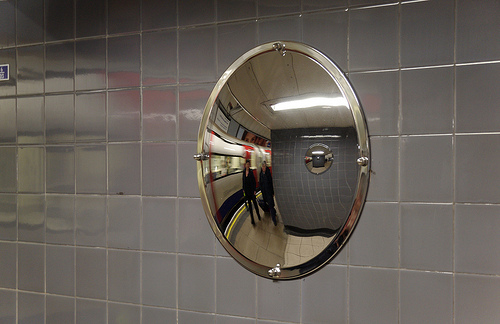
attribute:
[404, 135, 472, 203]
tiles — bluish gray 